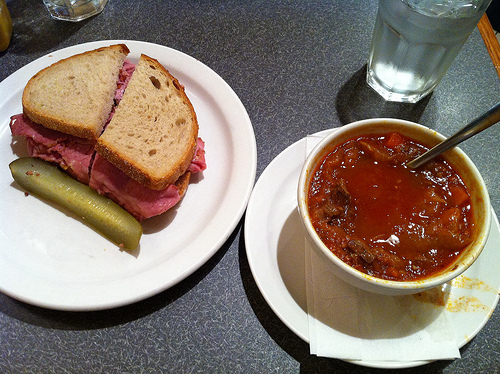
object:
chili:
[304, 130, 478, 284]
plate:
[242, 125, 500, 374]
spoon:
[407, 101, 500, 170]